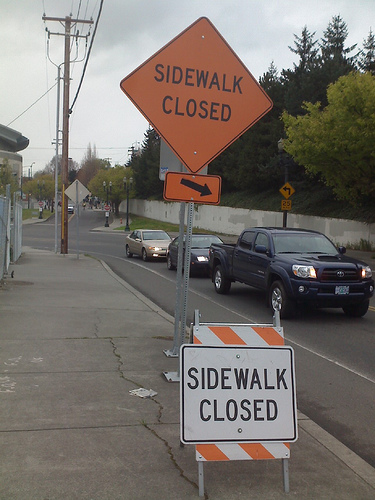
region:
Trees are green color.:
[282, 88, 349, 161]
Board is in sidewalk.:
[157, 354, 308, 491]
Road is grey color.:
[323, 311, 374, 362]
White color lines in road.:
[301, 332, 373, 417]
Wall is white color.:
[218, 197, 281, 244]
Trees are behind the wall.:
[197, 73, 363, 238]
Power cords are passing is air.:
[37, 7, 98, 92]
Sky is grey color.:
[17, 30, 108, 114]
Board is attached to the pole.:
[133, 34, 236, 254]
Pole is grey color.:
[152, 195, 201, 340]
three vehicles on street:
[106, 191, 371, 377]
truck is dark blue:
[191, 213, 370, 343]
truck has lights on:
[294, 257, 372, 294]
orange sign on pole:
[147, 163, 227, 354]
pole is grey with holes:
[168, 201, 197, 357]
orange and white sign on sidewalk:
[159, 288, 314, 495]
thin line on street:
[257, 300, 371, 405]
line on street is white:
[294, 333, 363, 399]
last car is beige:
[118, 218, 171, 264]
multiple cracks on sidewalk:
[84, 295, 186, 480]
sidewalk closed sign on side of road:
[125, 15, 273, 174]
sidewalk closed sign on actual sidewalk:
[178, 309, 296, 495]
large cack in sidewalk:
[87, 303, 215, 498]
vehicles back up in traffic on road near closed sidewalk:
[119, 219, 370, 319]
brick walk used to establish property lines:
[116, 192, 368, 250]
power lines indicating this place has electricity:
[37, 11, 98, 249]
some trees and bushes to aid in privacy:
[119, 20, 370, 209]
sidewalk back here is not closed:
[96, 201, 122, 231]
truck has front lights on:
[291, 263, 371, 283]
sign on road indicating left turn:
[277, 180, 296, 219]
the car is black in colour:
[197, 202, 360, 354]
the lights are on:
[290, 262, 373, 285]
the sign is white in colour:
[155, 339, 318, 445]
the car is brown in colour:
[113, 213, 170, 255]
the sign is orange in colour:
[130, 14, 275, 230]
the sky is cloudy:
[113, 18, 126, 56]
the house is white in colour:
[4, 144, 28, 273]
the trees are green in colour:
[320, 68, 356, 192]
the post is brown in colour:
[51, 14, 78, 250]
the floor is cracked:
[40, 339, 173, 485]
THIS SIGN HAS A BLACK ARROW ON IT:
[157, 162, 225, 210]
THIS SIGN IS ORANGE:
[158, 162, 228, 216]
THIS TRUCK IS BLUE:
[206, 220, 371, 321]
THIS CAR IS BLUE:
[165, 229, 232, 282]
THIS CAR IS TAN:
[120, 225, 180, 265]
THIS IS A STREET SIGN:
[62, 176, 99, 268]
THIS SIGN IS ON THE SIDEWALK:
[168, 338, 310, 459]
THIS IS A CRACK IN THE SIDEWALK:
[94, 315, 201, 496]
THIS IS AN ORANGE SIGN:
[111, 11, 276, 168]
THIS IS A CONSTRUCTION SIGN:
[179, 311, 302, 499]